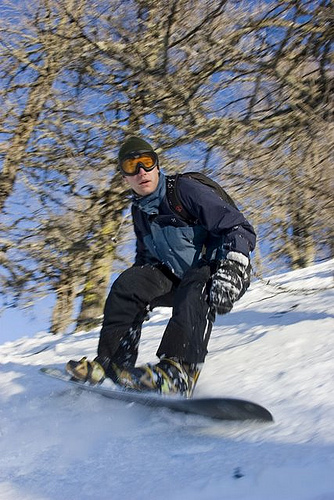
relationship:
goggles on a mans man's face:
[118, 150, 158, 174] [121, 149, 159, 197]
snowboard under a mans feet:
[34, 367, 279, 430] [60, 338, 205, 399]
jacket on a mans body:
[132, 180, 259, 275] [92, 177, 256, 361]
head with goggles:
[120, 136, 161, 197] [119, 151, 158, 175]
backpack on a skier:
[167, 168, 252, 238] [64, 137, 257, 398]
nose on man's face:
[134, 166, 148, 178] [117, 149, 161, 191]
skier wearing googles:
[64, 137, 257, 398] [117, 148, 158, 175]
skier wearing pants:
[60, 123, 266, 399] [79, 263, 225, 367]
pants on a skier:
[77, 256, 231, 370] [64, 137, 257, 398]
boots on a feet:
[66, 353, 202, 399] [42, 350, 222, 400]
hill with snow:
[12, 226, 321, 496] [252, 346, 330, 387]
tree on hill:
[214, 1, 333, 270] [1, 255, 333, 497]